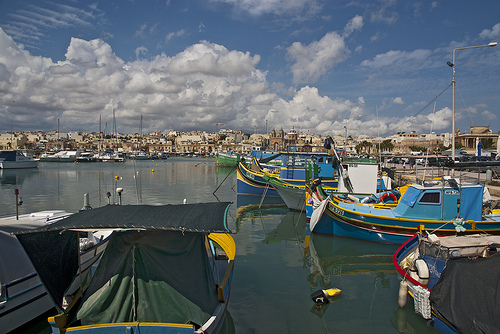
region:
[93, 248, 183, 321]
the tarp is green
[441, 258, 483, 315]
the tarp is black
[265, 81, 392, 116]
the sky is really cloudy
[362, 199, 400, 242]
boat has yellow stripe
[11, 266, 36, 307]
white boat in water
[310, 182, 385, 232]
the boat is blue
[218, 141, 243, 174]
the boat is green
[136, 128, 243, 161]
buildings in the background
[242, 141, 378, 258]
boats are tied up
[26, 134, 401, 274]
a lot of boats are present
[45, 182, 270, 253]
The umbrella is black.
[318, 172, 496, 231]
The boat is blue.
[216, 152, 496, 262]
The boats are colorful.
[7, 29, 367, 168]
The clouds are white and fluffy.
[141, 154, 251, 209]
The water is clear.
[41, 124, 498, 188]
The houses are in the back.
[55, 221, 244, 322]
The boat has a green cover.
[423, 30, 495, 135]
The light is metal.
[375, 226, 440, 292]
The trim is red.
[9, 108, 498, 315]
Many boats are on the water.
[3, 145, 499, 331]
many boats in the ocean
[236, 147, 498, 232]
the boats are brightly colored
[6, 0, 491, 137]
the sky is full of clouds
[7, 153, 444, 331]
the water is green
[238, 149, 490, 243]
the boats are blue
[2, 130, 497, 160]
many building in the distance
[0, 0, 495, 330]
the scene takes place outdoors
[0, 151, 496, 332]
the boats are in the marina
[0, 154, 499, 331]
the boats are in the harbor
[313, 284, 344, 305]
a yellow object in the water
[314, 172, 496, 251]
a blue yellow red and black boat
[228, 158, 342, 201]
a blue yellow red and black boat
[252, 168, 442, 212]
a blue yellow red and black boat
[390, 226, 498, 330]
a blue yellow red and black boat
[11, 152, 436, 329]
a body of water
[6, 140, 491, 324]
a large boat marina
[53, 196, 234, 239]
a dark green canopy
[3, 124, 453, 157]
a large town in distance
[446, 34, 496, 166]
a tall electric light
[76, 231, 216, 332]
a green plastic tarp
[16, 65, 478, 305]
A marina scene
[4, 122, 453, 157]
A town is in the background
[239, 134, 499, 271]
Boats are docked here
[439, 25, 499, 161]
This is a light pole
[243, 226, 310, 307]
The water is calm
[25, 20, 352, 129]
The sky is cloudy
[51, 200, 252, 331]
This boat has a cover over it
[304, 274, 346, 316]
A buoy is floating here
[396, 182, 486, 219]
This is the boat's cabin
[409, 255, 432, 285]
A life preserver